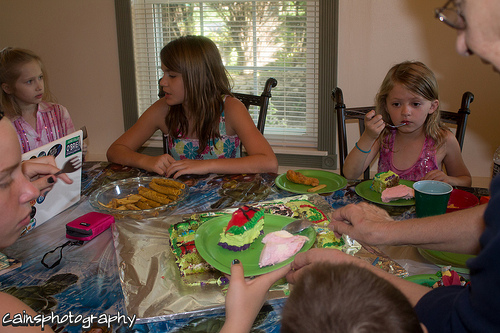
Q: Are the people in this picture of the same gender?
A: No, they are both male and female.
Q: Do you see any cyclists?
A: No, there are no cyclists.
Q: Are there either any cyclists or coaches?
A: No, there are no cyclists or coaches.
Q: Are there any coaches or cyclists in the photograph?
A: No, there are no cyclists or coaches.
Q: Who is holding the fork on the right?
A: The girl is holding the fork.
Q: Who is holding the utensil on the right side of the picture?
A: The girl is holding the fork.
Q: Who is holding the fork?
A: The girl is holding the fork.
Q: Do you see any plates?
A: Yes, there is a plate.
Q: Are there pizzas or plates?
A: Yes, there is a plate.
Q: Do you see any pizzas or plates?
A: Yes, there is a plate.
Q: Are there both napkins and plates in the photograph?
A: No, there is a plate but no napkins.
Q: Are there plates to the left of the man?
A: Yes, there is a plate to the left of the man.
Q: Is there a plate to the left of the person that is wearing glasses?
A: Yes, there is a plate to the left of the man.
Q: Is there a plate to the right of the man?
A: No, the plate is to the left of the man.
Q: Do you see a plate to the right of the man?
A: No, the plate is to the left of the man.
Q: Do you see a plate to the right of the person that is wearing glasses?
A: No, the plate is to the left of the man.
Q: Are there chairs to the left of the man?
A: No, there is a plate to the left of the man.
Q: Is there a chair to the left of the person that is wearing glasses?
A: No, there is a plate to the left of the man.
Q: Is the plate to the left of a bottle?
A: No, the plate is to the left of the man.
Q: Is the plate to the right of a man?
A: No, the plate is to the left of a man.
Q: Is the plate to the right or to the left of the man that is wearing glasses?
A: The plate is to the left of the man.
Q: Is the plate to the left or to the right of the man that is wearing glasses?
A: The plate is to the left of the man.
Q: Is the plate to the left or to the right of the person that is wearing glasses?
A: The plate is to the left of the man.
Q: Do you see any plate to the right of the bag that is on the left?
A: Yes, there is a plate to the right of the bag.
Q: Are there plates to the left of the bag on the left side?
A: No, the plate is to the right of the bag.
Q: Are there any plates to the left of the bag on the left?
A: No, the plate is to the right of the bag.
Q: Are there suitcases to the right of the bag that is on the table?
A: No, there is a plate to the right of the bag.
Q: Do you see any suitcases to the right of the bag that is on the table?
A: No, there is a plate to the right of the bag.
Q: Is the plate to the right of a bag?
A: Yes, the plate is to the right of a bag.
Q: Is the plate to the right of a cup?
A: No, the plate is to the right of a bag.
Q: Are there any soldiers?
A: No, there are no soldiers.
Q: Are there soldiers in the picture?
A: No, there are no soldiers.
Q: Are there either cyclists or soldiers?
A: No, there are no soldiers or cyclists.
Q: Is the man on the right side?
A: Yes, the man is on the right of the image.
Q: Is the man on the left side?
A: No, the man is on the right of the image.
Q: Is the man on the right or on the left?
A: The man is on the right of the image.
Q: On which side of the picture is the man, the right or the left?
A: The man is on the right of the image.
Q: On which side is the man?
A: The man is on the right of the image.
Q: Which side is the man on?
A: The man is on the right of the image.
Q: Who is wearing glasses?
A: The man is wearing glasses.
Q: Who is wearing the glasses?
A: The man is wearing glasses.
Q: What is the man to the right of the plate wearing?
A: The man is wearing glasses.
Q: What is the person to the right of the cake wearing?
A: The man is wearing glasses.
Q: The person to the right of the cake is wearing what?
A: The man is wearing glasses.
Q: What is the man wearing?
A: The man is wearing glasses.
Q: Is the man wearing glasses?
A: Yes, the man is wearing glasses.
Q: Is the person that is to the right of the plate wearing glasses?
A: Yes, the man is wearing glasses.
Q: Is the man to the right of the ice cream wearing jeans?
A: No, the man is wearing glasses.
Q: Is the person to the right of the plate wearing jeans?
A: No, the man is wearing glasses.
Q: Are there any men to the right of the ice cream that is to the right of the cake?
A: Yes, there is a man to the right of the ice cream.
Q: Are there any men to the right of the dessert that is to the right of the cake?
A: Yes, there is a man to the right of the ice cream.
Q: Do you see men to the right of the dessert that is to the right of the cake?
A: Yes, there is a man to the right of the ice cream.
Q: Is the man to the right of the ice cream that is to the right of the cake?
A: Yes, the man is to the right of the ice cream.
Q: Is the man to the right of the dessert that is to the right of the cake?
A: Yes, the man is to the right of the ice cream.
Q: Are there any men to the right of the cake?
A: Yes, there is a man to the right of the cake.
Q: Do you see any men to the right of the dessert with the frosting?
A: Yes, there is a man to the right of the cake.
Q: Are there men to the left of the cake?
A: No, the man is to the right of the cake.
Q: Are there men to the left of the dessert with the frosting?
A: No, the man is to the right of the cake.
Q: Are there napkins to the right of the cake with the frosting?
A: No, there is a man to the right of the cake.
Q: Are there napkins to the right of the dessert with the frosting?
A: No, there is a man to the right of the cake.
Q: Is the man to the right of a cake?
A: Yes, the man is to the right of a cake.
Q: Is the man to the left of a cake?
A: No, the man is to the right of a cake.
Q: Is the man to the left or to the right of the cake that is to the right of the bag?
A: The man is to the right of the cake.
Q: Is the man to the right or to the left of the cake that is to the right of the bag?
A: The man is to the right of the cake.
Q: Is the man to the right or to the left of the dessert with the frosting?
A: The man is to the right of the cake.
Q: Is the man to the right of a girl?
A: Yes, the man is to the right of a girl.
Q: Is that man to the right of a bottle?
A: No, the man is to the right of a girl.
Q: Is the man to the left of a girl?
A: No, the man is to the right of a girl.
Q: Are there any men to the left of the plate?
A: No, the man is to the right of the plate.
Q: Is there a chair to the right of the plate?
A: No, there is a man to the right of the plate.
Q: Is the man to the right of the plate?
A: Yes, the man is to the right of the plate.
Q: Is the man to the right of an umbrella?
A: No, the man is to the right of the plate.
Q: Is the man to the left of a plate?
A: No, the man is to the right of a plate.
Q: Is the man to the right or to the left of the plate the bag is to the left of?
A: The man is to the right of the plate.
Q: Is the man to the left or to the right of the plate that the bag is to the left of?
A: The man is to the right of the plate.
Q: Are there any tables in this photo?
A: Yes, there is a table.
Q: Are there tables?
A: Yes, there is a table.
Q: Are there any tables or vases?
A: Yes, there is a table.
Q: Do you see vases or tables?
A: Yes, there is a table.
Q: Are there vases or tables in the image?
A: Yes, there is a table.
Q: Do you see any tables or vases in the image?
A: Yes, there is a table.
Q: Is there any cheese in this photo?
A: No, there is no cheese.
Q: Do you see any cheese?
A: No, there is no cheese.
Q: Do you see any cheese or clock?
A: No, there are no cheese or clocks.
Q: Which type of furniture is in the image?
A: The furniture is a table.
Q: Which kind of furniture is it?
A: The piece of furniture is a table.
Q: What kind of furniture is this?
A: That is a table.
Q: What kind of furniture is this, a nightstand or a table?
A: That is a table.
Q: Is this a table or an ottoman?
A: This is a table.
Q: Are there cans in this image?
A: No, there are no cans.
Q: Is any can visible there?
A: No, there are no cans.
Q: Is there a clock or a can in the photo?
A: No, there are no cans or clocks.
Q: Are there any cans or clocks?
A: No, there are no cans or clocks.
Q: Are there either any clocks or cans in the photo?
A: No, there are no cans or clocks.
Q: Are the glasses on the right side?
A: Yes, the glasses are on the right of the image.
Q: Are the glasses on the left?
A: No, the glasses are on the right of the image.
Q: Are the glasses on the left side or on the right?
A: The glasses are on the right of the image.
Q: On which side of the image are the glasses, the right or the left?
A: The glasses are on the right of the image.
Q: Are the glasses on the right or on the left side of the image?
A: The glasses are on the right of the image.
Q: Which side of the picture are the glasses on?
A: The glasses are on the right of the image.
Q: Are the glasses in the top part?
A: Yes, the glasses are in the top of the image.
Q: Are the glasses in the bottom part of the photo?
A: No, the glasses are in the top of the image.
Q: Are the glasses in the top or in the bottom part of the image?
A: The glasses are in the top of the image.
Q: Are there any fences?
A: No, there are no fences.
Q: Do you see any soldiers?
A: No, there are no soldiers.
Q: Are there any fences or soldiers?
A: No, there are no soldiers or fences.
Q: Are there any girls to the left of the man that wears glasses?
A: Yes, there is a girl to the left of the man.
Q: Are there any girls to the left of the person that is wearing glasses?
A: Yes, there is a girl to the left of the man.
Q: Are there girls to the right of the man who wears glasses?
A: No, the girl is to the left of the man.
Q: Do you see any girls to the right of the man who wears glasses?
A: No, the girl is to the left of the man.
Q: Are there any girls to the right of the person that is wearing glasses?
A: No, the girl is to the left of the man.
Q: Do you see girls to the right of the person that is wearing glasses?
A: No, the girl is to the left of the man.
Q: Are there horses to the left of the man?
A: No, there is a girl to the left of the man.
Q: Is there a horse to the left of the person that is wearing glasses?
A: No, there is a girl to the left of the man.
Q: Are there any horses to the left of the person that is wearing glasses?
A: No, there is a girl to the left of the man.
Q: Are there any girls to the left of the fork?
A: Yes, there is a girl to the left of the fork.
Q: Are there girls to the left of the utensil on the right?
A: Yes, there is a girl to the left of the fork.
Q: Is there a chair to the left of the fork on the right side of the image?
A: No, there is a girl to the left of the fork.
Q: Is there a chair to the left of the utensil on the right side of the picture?
A: No, there is a girl to the left of the fork.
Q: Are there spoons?
A: Yes, there is a spoon.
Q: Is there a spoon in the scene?
A: Yes, there is a spoon.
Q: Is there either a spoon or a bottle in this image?
A: Yes, there is a spoon.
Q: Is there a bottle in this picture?
A: No, there are no bottles.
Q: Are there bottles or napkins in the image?
A: No, there are no bottles or napkins.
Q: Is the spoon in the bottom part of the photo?
A: Yes, the spoon is in the bottom of the image.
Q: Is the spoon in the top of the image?
A: No, the spoon is in the bottom of the image.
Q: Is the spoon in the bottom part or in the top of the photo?
A: The spoon is in the bottom of the image.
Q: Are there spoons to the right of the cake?
A: Yes, there is a spoon to the right of the cake.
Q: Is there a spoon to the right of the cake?
A: Yes, there is a spoon to the right of the cake.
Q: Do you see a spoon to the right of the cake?
A: Yes, there is a spoon to the right of the cake.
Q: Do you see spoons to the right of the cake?
A: Yes, there is a spoon to the right of the cake.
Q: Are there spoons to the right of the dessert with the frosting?
A: Yes, there is a spoon to the right of the cake.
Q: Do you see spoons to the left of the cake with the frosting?
A: No, the spoon is to the right of the cake.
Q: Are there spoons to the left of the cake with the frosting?
A: No, the spoon is to the right of the cake.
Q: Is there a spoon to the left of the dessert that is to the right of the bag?
A: No, the spoon is to the right of the cake.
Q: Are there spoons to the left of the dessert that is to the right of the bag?
A: No, the spoon is to the right of the cake.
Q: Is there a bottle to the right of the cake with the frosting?
A: No, there is a spoon to the right of the cake.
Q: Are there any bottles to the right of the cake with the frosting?
A: No, there is a spoon to the right of the cake.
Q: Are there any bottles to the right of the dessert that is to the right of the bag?
A: No, there is a spoon to the right of the cake.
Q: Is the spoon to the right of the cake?
A: Yes, the spoon is to the right of the cake.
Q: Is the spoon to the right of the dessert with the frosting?
A: Yes, the spoon is to the right of the cake.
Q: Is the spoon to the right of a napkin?
A: No, the spoon is to the right of the cake.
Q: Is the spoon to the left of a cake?
A: No, the spoon is to the right of a cake.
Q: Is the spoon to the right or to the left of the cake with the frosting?
A: The spoon is to the right of the cake.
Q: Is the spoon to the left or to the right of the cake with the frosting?
A: The spoon is to the right of the cake.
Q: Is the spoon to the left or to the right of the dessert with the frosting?
A: The spoon is to the right of the cake.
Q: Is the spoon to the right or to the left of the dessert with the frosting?
A: The spoon is to the right of the cake.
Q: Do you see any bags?
A: Yes, there is a bag.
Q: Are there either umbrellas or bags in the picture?
A: Yes, there is a bag.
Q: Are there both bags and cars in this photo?
A: No, there is a bag but no cars.